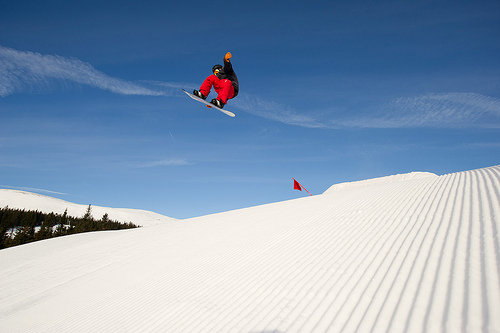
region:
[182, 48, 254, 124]
man in air snowboarding in red pants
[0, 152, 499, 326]
white expanse of snow with ridged pattern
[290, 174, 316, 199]
red flag on white ski slope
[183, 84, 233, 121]
white snowboard under man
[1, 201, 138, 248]
valley of green evergreen trees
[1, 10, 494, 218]
bright blue sunny sky with clouds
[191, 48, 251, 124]
man wearing orange glove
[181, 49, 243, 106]
black helmet on boy's head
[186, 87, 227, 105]
black shoes on boy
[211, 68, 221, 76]
yellow goggles on boy's face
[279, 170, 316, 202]
a red flag marking the course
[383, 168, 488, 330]
even tracks in the snow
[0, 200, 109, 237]
a thicket of green trees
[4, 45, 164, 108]
a sparse white cloud in the sky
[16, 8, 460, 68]
a clear blue winter sky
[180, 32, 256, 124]
a snowboarder performing a stunt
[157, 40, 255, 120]
a person wearing red pants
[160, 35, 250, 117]
a person wearing a black jacket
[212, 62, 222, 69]
a black helmet on a head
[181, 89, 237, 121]
a white snowboard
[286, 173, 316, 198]
Red flag in the snow.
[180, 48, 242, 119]
snowboarder in the air.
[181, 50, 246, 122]
Red snow pants on the person.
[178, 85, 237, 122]
White snowboard in the air.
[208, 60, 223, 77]
Goggles on the man.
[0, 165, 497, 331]
Snow covering the ground.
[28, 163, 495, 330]
Lines in the snow.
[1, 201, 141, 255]
Trees in the background.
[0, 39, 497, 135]
White clouds in the background.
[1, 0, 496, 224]
Blue sky in the background.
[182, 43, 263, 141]
this is a person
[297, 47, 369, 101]
the sky is clear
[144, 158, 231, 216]
the sky is clear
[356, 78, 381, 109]
the sky is clear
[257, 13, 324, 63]
the sky is clear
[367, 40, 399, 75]
the sky is clear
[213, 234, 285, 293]
this is snow on the ground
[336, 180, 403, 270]
this is snow on the ground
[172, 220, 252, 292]
this is snow on the ground